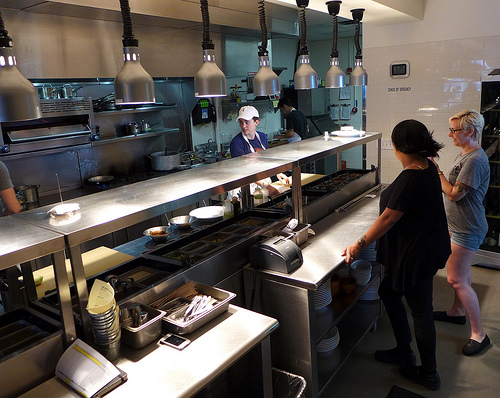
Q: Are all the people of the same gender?
A: Yes, all the people are female.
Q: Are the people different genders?
A: No, all the people are female.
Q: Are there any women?
A: Yes, there is a woman.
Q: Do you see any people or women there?
A: Yes, there is a woman.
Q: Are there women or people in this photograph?
A: Yes, there is a woman.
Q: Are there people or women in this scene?
A: Yes, there is a woman.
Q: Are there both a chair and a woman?
A: No, there is a woman but no chairs.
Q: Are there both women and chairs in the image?
A: No, there is a woman but no chairs.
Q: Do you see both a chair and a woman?
A: No, there is a woman but no chairs.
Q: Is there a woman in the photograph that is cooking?
A: Yes, there is a woman that is cooking.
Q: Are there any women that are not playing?
A: Yes, there is a woman that is cooking.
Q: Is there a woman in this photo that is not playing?
A: Yes, there is a woman that is cooking.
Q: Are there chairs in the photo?
A: No, there are no chairs.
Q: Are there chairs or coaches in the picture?
A: No, there are no chairs or coaches.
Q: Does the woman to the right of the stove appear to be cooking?
A: Yes, the woman is cooking.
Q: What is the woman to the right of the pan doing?
A: The woman is cooking.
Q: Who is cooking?
A: The woman is cooking.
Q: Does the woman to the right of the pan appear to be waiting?
A: No, the woman is cooking.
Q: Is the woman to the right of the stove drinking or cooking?
A: The woman is cooking.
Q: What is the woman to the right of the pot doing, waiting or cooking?
A: The woman is cooking.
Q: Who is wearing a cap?
A: The woman is wearing a cap.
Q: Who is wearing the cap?
A: The woman is wearing a cap.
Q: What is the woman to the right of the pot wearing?
A: The woman is wearing a cap.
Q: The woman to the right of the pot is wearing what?
A: The woman is wearing a cap.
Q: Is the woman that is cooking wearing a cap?
A: Yes, the woman is wearing a cap.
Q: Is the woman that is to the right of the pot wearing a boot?
A: No, the woman is wearing a cap.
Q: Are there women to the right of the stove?
A: Yes, there is a woman to the right of the stove.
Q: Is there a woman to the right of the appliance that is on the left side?
A: Yes, there is a woman to the right of the stove.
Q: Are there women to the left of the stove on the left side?
A: No, the woman is to the right of the stove.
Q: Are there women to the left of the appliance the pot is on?
A: No, the woman is to the right of the stove.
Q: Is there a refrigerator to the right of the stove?
A: No, there is a woman to the right of the stove.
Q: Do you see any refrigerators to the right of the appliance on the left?
A: No, there is a woman to the right of the stove.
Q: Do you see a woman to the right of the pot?
A: Yes, there is a woman to the right of the pot.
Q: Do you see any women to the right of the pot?
A: Yes, there is a woman to the right of the pot.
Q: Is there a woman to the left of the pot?
A: No, the woman is to the right of the pot.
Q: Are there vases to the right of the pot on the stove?
A: No, there is a woman to the right of the pot.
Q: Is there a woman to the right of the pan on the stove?
A: Yes, there is a woman to the right of the pan.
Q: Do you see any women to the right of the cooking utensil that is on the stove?
A: Yes, there is a woman to the right of the pan.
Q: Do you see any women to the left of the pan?
A: No, the woman is to the right of the pan.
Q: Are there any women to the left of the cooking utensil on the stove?
A: No, the woman is to the right of the pan.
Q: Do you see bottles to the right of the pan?
A: No, there is a woman to the right of the pan.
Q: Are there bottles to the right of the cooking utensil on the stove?
A: No, there is a woman to the right of the pan.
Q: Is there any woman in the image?
A: Yes, there is a woman.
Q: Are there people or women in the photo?
A: Yes, there is a woman.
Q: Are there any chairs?
A: No, there are no chairs.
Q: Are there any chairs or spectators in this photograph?
A: No, there are no chairs or spectators.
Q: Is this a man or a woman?
A: This is a woman.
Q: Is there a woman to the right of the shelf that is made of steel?
A: Yes, there is a woman to the right of the shelf.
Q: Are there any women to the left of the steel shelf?
A: No, the woman is to the right of the shelf.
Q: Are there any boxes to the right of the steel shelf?
A: No, there is a woman to the right of the shelf.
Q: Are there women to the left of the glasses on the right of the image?
A: Yes, there is a woman to the left of the glasses.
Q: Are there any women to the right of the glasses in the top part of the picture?
A: No, the woman is to the left of the glasses.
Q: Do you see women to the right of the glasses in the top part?
A: No, the woman is to the left of the glasses.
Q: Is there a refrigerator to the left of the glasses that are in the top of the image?
A: No, there is a woman to the left of the glasses.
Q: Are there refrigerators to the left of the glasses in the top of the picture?
A: No, there is a woman to the left of the glasses.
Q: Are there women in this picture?
A: Yes, there is a woman.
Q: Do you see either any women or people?
A: Yes, there is a woman.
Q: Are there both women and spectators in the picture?
A: No, there is a woman but no spectators.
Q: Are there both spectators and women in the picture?
A: No, there is a woman but no spectators.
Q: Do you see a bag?
A: No, there are no bags.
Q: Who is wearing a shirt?
A: The woman is wearing a shirt.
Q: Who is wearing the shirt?
A: The woman is wearing a shirt.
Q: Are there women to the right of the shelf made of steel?
A: Yes, there is a woman to the right of the shelf.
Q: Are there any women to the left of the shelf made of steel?
A: No, the woman is to the right of the shelf.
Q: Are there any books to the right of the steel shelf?
A: No, there is a woman to the right of the shelf.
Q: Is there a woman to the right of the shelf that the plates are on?
A: Yes, there is a woman to the right of the shelf.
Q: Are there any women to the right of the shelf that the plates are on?
A: Yes, there is a woman to the right of the shelf.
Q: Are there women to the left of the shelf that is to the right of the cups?
A: No, the woman is to the right of the shelf.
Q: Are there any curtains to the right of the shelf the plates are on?
A: No, there is a woman to the right of the shelf.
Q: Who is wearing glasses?
A: The woman is wearing glasses.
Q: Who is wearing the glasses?
A: The woman is wearing glasses.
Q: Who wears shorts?
A: The woman wears shorts.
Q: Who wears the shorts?
A: The woman wears shorts.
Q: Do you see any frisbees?
A: No, there are no frisbees.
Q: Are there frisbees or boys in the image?
A: No, there are no frisbees or boys.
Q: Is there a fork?
A: No, there are no forks.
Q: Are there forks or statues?
A: No, there are no forks or statues.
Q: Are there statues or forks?
A: No, there are no forks or statues.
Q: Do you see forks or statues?
A: No, there are no forks or statues.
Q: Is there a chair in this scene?
A: No, there are no chairs.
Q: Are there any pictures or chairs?
A: No, there are no chairs or pictures.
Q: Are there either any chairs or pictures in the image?
A: No, there are no chairs or pictures.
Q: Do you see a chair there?
A: No, there are no chairs.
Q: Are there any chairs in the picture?
A: No, there are no chairs.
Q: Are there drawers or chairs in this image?
A: No, there are no chairs or drawers.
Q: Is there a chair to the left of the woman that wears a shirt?
A: No, there is a shelf to the left of the woman.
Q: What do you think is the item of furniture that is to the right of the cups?
A: The piece of furniture is a shelf.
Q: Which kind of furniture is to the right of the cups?
A: The piece of furniture is a shelf.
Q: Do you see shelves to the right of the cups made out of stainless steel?
A: Yes, there is a shelf to the right of the cups.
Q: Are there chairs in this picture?
A: No, there are no chairs.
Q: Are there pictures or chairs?
A: No, there are no chairs or pictures.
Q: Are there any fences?
A: No, there are no fences.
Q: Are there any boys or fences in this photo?
A: No, there are no fences or boys.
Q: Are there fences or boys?
A: No, there are no fences or boys.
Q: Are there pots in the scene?
A: Yes, there is a pot.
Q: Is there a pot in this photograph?
A: Yes, there is a pot.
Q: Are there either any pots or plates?
A: Yes, there is a pot.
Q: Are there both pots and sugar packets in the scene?
A: No, there is a pot but no sugar packets.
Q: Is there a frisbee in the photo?
A: No, there are no frisbees.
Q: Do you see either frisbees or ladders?
A: No, there are no frisbees or ladders.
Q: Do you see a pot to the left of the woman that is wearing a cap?
A: Yes, there is a pot to the left of the woman.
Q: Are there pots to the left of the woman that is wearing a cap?
A: Yes, there is a pot to the left of the woman.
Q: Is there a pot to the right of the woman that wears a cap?
A: No, the pot is to the left of the woman.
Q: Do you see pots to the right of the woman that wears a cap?
A: No, the pot is to the left of the woman.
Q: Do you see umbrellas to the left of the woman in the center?
A: No, there is a pot to the left of the woman.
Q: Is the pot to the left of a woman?
A: Yes, the pot is to the left of a woman.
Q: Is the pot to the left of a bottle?
A: No, the pot is to the left of a woman.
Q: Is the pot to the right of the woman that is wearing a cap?
A: No, the pot is to the left of the woman.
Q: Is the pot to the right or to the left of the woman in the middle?
A: The pot is to the left of the woman.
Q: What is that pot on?
A: The pot is on the stove.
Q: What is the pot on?
A: The pot is on the stove.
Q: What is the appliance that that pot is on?
A: The appliance is a stove.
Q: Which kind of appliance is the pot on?
A: The pot is on the stove.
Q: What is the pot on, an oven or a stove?
A: The pot is on a stove.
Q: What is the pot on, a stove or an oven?
A: The pot is on a stove.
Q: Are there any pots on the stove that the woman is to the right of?
A: Yes, there is a pot on the stove.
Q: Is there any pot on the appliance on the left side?
A: Yes, there is a pot on the stove.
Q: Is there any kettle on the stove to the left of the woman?
A: No, there is a pot on the stove.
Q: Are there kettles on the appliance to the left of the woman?
A: No, there is a pot on the stove.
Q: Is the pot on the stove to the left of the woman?
A: Yes, the pot is on the stove.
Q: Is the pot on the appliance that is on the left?
A: Yes, the pot is on the stove.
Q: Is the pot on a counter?
A: No, the pot is on the stove.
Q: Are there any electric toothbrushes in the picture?
A: No, there are no electric toothbrushes.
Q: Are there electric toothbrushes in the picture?
A: No, there are no electric toothbrushes.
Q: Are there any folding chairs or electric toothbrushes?
A: No, there are no electric toothbrushes or folding chairs.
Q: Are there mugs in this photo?
A: No, there are no mugs.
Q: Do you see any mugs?
A: No, there are no mugs.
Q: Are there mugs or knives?
A: No, there are no mugs or knives.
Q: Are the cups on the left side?
A: Yes, the cups are on the left of the image.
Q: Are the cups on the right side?
A: No, the cups are on the left of the image.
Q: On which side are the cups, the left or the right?
A: The cups are on the left of the image.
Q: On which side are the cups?
A: The cups are on the left of the image.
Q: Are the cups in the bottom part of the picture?
A: Yes, the cups are in the bottom of the image.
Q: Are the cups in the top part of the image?
A: No, the cups are in the bottom of the image.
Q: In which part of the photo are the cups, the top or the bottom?
A: The cups are in the bottom of the image.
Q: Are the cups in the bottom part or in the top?
A: The cups are in the bottom of the image.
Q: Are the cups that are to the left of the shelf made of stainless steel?
A: Yes, the cups are made of stainless steel.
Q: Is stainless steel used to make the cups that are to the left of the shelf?
A: Yes, the cups are made of stainless steel.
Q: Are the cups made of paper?
A: No, the cups are made of stainless steel.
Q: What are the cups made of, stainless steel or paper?
A: The cups are made of stainless steel.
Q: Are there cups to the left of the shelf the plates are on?
A: Yes, there are cups to the left of the shelf.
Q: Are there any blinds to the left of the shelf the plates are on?
A: No, there are cups to the left of the shelf.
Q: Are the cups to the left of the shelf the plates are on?
A: Yes, the cups are to the left of the shelf.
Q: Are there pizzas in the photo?
A: No, there are no pizzas.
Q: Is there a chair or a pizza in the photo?
A: No, there are no pizzas or chairs.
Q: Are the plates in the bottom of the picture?
A: Yes, the plates are in the bottom of the image.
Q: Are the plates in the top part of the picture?
A: No, the plates are in the bottom of the image.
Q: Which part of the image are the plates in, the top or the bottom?
A: The plates are in the bottom of the image.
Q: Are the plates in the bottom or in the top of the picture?
A: The plates are in the bottom of the image.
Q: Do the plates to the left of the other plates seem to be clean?
A: Yes, the plates are clean.